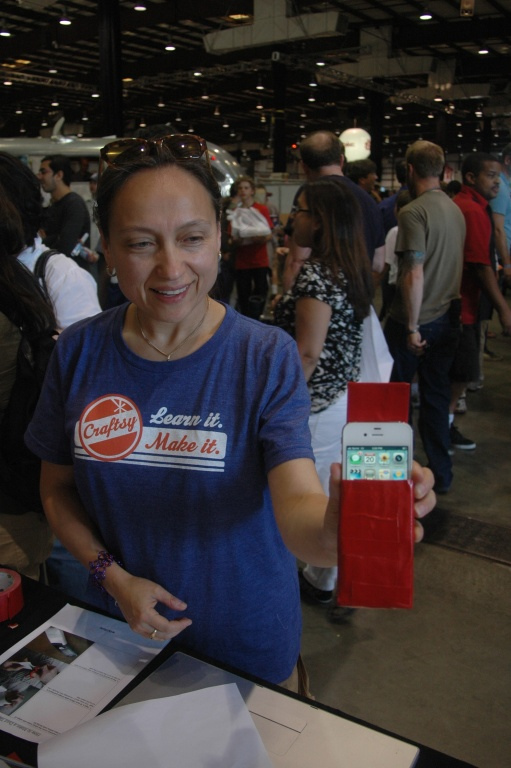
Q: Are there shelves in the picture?
A: No, there are no shelves.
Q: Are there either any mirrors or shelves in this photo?
A: No, there are no shelves or mirrors.